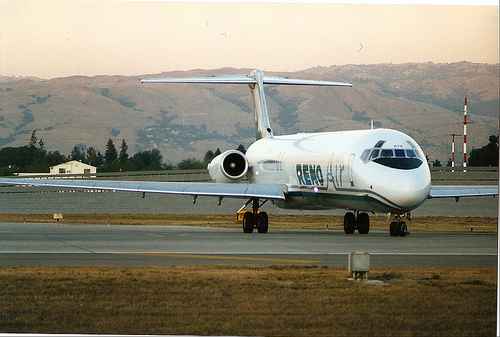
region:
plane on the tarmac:
[1, 56, 499, 251]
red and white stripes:
[458, 93, 477, 176]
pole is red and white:
[446, 131, 458, 173]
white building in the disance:
[8, 153, 105, 187]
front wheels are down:
[387, 212, 412, 237]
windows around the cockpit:
[358, 139, 428, 175]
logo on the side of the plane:
[289, 146, 354, 189]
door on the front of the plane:
[341, 144, 361, 184]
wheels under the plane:
[236, 203, 272, 233]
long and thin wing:
[2, 166, 284, 211]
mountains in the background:
[6, 51, 497, 125]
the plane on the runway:
[5, 59, 498, 259]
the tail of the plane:
[116, 68, 353, 134]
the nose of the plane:
[383, 180, 424, 209]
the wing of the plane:
[1, 173, 283, 204]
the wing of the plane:
[427, 175, 497, 201]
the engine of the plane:
[195, 144, 259, 182]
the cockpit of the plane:
[352, 133, 422, 168]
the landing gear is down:
[234, 205, 420, 242]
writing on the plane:
[295, 156, 354, 201]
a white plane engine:
[208, 144, 254, 181]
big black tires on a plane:
[236, 198, 273, 235]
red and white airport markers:
[448, 96, 470, 174]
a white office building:
[48, 161, 97, 179]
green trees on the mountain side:
[108, 124, 120, 139]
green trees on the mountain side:
[16, 97, 33, 134]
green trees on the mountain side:
[388, 81, 458, 108]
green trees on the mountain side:
[210, 89, 252, 119]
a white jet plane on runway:
[2, 69, 499, 241]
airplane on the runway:
[57, 73, 467, 256]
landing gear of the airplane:
[218, 198, 420, 246]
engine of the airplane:
[213, 139, 248, 186]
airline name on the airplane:
[291, 160, 351, 188]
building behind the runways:
[40, 155, 97, 174]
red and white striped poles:
[433, 94, 477, 179]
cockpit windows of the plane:
[368, 145, 423, 160]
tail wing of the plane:
[131, 67, 353, 90]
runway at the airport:
[18, 223, 200, 248]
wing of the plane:
[1, 169, 286, 210]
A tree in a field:
[118, 139, 138, 168]